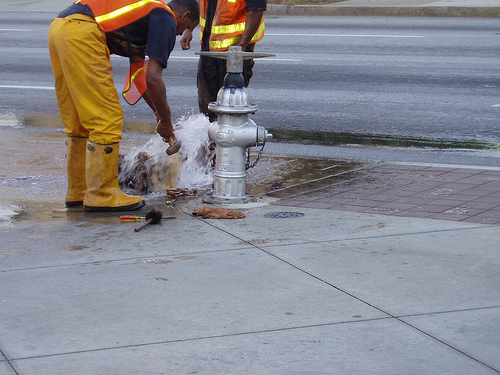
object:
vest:
[196, 0, 266, 56]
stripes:
[209, 22, 246, 35]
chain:
[250, 140, 271, 168]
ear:
[176, 9, 193, 22]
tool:
[163, 133, 181, 157]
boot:
[63, 132, 86, 210]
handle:
[193, 44, 275, 72]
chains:
[242, 145, 251, 173]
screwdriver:
[116, 214, 177, 223]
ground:
[0, 0, 499, 374]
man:
[46, 0, 200, 213]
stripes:
[204, 21, 268, 52]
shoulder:
[150, 4, 179, 31]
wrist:
[156, 109, 173, 123]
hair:
[166, 0, 200, 25]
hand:
[152, 117, 178, 141]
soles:
[82, 199, 146, 220]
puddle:
[258, 127, 490, 152]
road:
[0, 10, 499, 166]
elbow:
[142, 72, 164, 92]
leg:
[47, 24, 89, 192]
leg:
[53, 27, 126, 192]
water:
[116, 109, 211, 197]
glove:
[187, 204, 245, 222]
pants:
[45, 11, 123, 148]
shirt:
[52, 1, 179, 68]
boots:
[80, 139, 147, 215]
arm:
[138, 27, 172, 119]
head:
[165, 0, 202, 37]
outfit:
[75, 0, 178, 107]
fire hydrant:
[193, 44, 273, 206]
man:
[177, 0, 266, 166]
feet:
[78, 185, 144, 214]